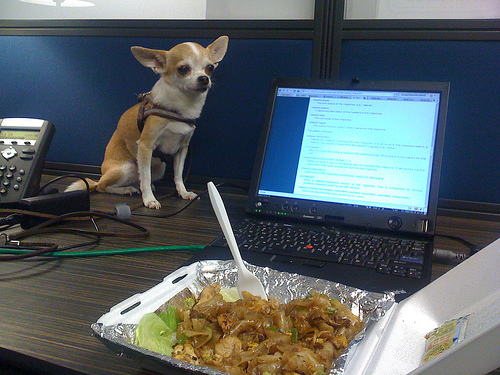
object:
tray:
[88, 235, 499, 375]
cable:
[206, 178, 481, 252]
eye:
[176, 63, 193, 76]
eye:
[204, 63, 216, 75]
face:
[166, 42, 217, 93]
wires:
[0, 209, 151, 265]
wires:
[211, 178, 249, 190]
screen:
[254, 86, 440, 216]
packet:
[419, 312, 472, 366]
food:
[138, 282, 364, 375]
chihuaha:
[61, 30, 234, 211]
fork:
[196, 181, 273, 304]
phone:
[0, 115, 56, 205]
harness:
[131, 89, 201, 167]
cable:
[59, 245, 201, 258]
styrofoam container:
[361, 241, 499, 375]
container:
[87, 234, 500, 375]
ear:
[129, 44, 169, 75]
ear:
[202, 34, 230, 64]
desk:
[0, 161, 500, 375]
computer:
[175, 77, 451, 309]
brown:
[22, 277, 85, 328]